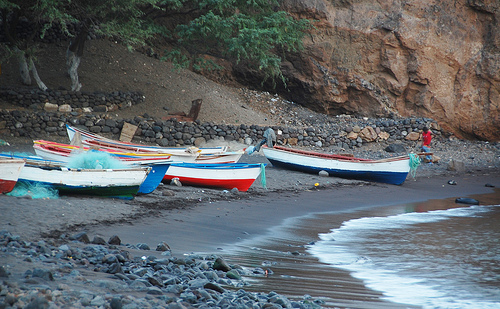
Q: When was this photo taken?
A: During the day.